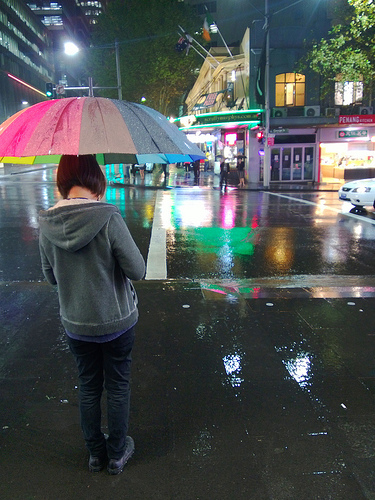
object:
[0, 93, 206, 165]
umbrella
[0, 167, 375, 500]
street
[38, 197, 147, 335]
jacket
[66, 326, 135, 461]
pants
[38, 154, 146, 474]
girl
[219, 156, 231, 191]
people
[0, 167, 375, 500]
sidewalk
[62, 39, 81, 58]
light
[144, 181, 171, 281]
line